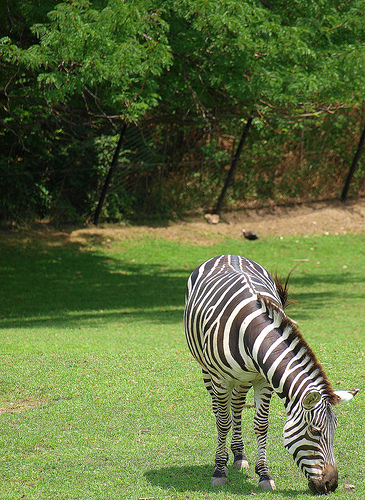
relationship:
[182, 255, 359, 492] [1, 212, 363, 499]
zebra on grass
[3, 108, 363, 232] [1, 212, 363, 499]
fence encloses grass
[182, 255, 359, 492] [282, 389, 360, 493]
zebra has bent head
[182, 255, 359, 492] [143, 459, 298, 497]
zebra has a shadow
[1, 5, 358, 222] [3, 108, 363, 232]
trees behind fence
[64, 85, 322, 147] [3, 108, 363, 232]
branches over fence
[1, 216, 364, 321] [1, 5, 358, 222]
shade from trees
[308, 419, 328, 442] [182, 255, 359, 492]
eye of zebra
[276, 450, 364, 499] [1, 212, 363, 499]
grazing on grass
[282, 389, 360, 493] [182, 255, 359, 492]
head of zebra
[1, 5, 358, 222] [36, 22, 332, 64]
trees with green leaves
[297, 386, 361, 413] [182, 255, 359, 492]
ears if zebra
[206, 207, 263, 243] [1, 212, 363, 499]
rocks near grass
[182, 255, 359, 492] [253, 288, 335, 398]
zebra has a mane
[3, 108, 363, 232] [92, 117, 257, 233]
fence has posts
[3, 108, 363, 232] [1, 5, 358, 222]
fence in front of trees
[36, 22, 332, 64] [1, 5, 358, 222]
green leaves on trees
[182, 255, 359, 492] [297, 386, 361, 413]
zebra shows h ears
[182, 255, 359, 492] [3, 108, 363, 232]
zebra inside fence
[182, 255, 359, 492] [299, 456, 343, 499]
zebra bends to graze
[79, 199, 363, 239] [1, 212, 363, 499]
dirt near grass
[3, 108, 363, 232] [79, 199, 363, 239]
fence next to dirt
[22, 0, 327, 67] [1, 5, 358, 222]
sun on trees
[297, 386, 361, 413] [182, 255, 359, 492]
ears on zebra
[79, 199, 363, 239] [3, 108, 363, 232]
dirt before fence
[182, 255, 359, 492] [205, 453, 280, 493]
zebra has hooves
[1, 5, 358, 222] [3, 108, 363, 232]
trees outside fence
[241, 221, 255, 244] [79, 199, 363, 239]
rock in dirt